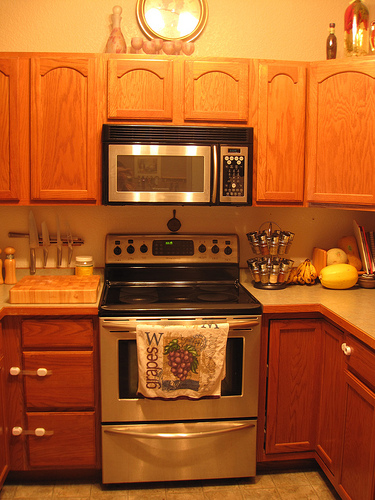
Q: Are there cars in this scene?
A: No, there are no cars.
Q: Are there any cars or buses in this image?
A: No, there are no cars or buses.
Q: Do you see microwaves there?
A: Yes, there is a microwave.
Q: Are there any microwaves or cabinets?
A: Yes, there is a microwave.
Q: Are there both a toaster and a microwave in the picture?
A: No, there is a microwave but no toasters.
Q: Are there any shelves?
A: No, there are no shelves.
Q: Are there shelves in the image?
A: No, there are no shelves.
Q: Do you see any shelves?
A: No, there are no shelves.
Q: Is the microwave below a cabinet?
A: Yes, the microwave is below a cabinet.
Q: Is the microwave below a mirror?
A: No, the microwave is below a cabinet.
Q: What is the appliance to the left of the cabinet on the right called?
A: The appliance is a microwave.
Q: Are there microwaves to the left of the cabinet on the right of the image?
A: Yes, there is a microwave to the left of the cabinet.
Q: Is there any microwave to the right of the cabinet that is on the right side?
A: No, the microwave is to the left of the cabinet.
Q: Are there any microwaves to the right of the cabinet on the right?
A: No, the microwave is to the left of the cabinet.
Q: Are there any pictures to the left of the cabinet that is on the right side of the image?
A: No, there is a microwave to the left of the cabinet.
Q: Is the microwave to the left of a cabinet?
A: Yes, the microwave is to the left of a cabinet.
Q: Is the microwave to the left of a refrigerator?
A: No, the microwave is to the left of a cabinet.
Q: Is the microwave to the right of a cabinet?
A: No, the microwave is to the left of a cabinet.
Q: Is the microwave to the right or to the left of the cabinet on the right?
A: The microwave is to the left of the cabinet.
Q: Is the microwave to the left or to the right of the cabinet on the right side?
A: The microwave is to the left of the cabinet.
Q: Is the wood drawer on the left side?
A: Yes, the drawer is on the left of the image.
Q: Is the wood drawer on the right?
A: No, the drawer is on the left of the image.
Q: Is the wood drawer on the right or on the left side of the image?
A: The drawer is on the left of the image.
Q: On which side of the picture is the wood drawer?
A: The drawer is on the left of the image.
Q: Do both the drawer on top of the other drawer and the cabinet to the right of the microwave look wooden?
A: Yes, both the drawer and the cabinet are wooden.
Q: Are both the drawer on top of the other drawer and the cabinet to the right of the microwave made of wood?
A: Yes, both the drawer and the cabinet are made of wood.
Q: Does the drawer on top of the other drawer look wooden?
A: Yes, the drawer is wooden.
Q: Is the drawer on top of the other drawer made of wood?
A: Yes, the drawer is made of wood.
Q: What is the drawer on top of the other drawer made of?
A: The drawer is made of wood.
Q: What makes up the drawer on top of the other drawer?
A: The drawer is made of wood.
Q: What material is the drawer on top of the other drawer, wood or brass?
A: The drawer is made of wood.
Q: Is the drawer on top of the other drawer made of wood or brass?
A: The drawer is made of wood.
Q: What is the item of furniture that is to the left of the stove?
A: The piece of furniture is a drawer.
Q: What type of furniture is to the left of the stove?
A: The piece of furniture is a drawer.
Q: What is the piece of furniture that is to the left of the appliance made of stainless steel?
A: The piece of furniture is a drawer.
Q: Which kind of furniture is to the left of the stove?
A: The piece of furniture is a drawer.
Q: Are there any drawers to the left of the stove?
A: Yes, there is a drawer to the left of the stove.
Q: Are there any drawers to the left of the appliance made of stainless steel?
A: Yes, there is a drawer to the left of the stove.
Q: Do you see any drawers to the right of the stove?
A: No, the drawer is to the left of the stove.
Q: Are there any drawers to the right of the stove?
A: No, the drawer is to the left of the stove.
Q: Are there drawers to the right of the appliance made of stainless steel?
A: No, the drawer is to the left of the stove.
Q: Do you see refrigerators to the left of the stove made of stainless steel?
A: No, there is a drawer to the left of the stove.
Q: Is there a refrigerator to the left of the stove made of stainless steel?
A: No, there is a drawer to the left of the stove.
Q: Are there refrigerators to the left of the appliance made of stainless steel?
A: No, there is a drawer to the left of the stove.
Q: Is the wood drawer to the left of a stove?
A: Yes, the drawer is to the left of a stove.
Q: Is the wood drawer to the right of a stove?
A: No, the drawer is to the left of a stove.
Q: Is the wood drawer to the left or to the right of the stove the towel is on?
A: The drawer is to the left of the stove.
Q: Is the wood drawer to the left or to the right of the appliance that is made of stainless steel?
A: The drawer is to the left of the stove.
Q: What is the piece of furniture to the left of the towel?
A: The piece of furniture is a drawer.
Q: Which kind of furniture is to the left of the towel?
A: The piece of furniture is a drawer.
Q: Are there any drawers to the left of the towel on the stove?
A: Yes, there is a drawer to the left of the towel.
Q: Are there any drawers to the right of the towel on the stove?
A: No, the drawer is to the left of the towel.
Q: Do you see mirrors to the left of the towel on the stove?
A: No, there is a drawer to the left of the towel.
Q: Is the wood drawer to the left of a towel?
A: Yes, the drawer is to the left of a towel.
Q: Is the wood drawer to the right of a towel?
A: No, the drawer is to the left of a towel.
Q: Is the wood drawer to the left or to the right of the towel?
A: The drawer is to the left of the towel.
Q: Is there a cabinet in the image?
A: Yes, there is a cabinet.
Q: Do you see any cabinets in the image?
A: Yes, there is a cabinet.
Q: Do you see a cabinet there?
A: Yes, there is a cabinet.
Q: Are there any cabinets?
A: Yes, there is a cabinet.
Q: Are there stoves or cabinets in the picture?
A: Yes, there is a cabinet.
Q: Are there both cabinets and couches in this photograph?
A: No, there is a cabinet but no couches.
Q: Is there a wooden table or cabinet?
A: Yes, there is a wood cabinet.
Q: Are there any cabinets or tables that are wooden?
A: Yes, the cabinet is wooden.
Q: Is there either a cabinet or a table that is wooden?
A: Yes, the cabinet is wooden.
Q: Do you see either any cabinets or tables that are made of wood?
A: Yes, the cabinet is made of wood.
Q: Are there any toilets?
A: No, there are no toilets.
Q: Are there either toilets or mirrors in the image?
A: No, there are no toilets or mirrors.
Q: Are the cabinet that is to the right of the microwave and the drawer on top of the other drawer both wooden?
A: Yes, both the cabinet and the drawer are wooden.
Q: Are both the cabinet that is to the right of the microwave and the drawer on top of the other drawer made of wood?
A: Yes, both the cabinet and the drawer are made of wood.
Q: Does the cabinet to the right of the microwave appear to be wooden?
A: Yes, the cabinet is wooden.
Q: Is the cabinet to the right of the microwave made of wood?
A: Yes, the cabinet is made of wood.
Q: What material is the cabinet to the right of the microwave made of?
A: The cabinet is made of wood.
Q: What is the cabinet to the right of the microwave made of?
A: The cabinet is made of wood.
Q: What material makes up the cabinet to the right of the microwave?
A: The cabinet is made of wood.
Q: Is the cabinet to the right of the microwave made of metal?
A: No, the cabinet is made of wood.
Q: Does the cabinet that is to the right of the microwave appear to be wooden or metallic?
A: The cabinet is wooden.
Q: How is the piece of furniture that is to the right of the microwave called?
A: The piece of furniture is a cabinet.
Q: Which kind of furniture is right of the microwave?
A: The piece of furniture is a cabinet.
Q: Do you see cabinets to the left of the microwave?
A: No, the cabinet is to the right of the microwave.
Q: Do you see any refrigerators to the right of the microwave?
A: No, there is a cabinet to the right of the microwave.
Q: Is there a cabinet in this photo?
A: Yes, there is a cabinet.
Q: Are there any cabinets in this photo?
A: Yes, there is a cabinet.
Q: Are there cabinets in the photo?
A: Yes, there is a cabinet.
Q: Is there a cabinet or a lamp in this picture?
A: Yes, there is a cabinet.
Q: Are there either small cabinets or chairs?
A: Yes, there is a small cabinet.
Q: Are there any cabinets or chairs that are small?
A: Yes, the cabinet is small.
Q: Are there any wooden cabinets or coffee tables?
A: Yes, there is a wood cabinet.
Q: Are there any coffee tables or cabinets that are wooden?
A: Yes, the cabinet is wooden.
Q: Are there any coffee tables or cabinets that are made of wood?
A: Yes, the cabinet is made of wood.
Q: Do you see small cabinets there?
A: Yes, there is a small cabinet.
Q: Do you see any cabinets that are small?
A: Yes, there is a small cabinet.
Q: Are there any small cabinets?
A: Yes, there is a small cabinet.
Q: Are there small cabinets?
A: Yes, there is a small cabinet.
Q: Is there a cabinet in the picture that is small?
A: Yes, there is a cabinet that is small.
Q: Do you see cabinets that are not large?
A: Yes, there is a small cabinet.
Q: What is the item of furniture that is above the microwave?
A: The piece of furniture is a cabinet.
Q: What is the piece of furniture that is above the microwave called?
A: The piece of furniture is a cabinet.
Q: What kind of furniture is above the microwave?
A: The piece of furniture is a cabinet.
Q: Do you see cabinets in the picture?
A: Yes, there is a cabinet.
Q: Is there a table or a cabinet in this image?
A: Yes, there is a cabinet.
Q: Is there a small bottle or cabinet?
A: Yes, there is a small cabinet.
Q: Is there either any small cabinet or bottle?
A: Yes, there is a small cabinet.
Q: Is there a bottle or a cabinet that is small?
A: Yes, the cabinet is small.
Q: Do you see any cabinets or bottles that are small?
A: Yes, the cabinet is small.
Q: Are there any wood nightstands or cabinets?
A: Yes, there is a wood cabinet.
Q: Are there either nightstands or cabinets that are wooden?
A: Yes, the cabinet is wooden.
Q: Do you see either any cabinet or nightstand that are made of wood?
A: Yes, the cabinet is made of wood.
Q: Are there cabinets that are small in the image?
A: Yes, there is a small cabinet.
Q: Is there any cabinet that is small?
A: Yes, there is a cabinet that is small.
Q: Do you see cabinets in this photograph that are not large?
A: Yes, there is a small cabinet.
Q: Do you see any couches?
A: No, there are no couches.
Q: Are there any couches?
A: No, there are no couches.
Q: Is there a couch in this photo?
A: No, there are no couches.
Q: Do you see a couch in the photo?
A: No, there are no couches.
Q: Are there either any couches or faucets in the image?
A: No, there are no couches or faucets.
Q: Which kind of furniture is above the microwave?
A: The piece of furniture is a cabinet.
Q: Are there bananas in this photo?
A: Yes, there are bananas.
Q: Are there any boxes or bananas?
A: Yes, there are bananas.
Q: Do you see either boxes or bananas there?
A: Yes, there are bananas.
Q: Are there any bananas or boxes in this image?
A: Yes, there are bananas.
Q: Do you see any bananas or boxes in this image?
A: Yes, there are bananas.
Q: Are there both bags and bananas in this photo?
A: No, there are bananas but no bags.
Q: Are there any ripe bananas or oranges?
A: Yes, there are ripe bananas.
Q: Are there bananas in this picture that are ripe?
A: Yes, there are ripe bananas.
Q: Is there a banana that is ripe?
A: Yes, there are bananas that are ripe.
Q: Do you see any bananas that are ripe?
A: Yes, there are bananas that are ripe.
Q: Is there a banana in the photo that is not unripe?
A: Yes, there are ripe bananas.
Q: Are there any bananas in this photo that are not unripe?
A: Yes, there are ripe bananas.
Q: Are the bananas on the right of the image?
A: Yes, the bananas are on the right of the image.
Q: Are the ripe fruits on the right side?
A: Yes, the bananas are on the right of the image.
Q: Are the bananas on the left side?
A: No, the bananas are on the right of the image.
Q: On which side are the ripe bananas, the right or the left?
A: The bananas are on the right of the image.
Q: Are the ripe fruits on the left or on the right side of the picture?
A: The bananas are on the right of the image.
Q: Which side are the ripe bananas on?
A: The bananas are on the right of the image.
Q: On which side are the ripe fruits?
A: The bananas are on the right of the image.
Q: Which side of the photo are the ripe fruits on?
A: The bananas are on the right of the image.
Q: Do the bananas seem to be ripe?
A: Yes, the bananas are ripe.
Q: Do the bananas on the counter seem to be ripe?
A: Yes, the bananas are ripe.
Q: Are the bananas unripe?
A: No, the bananas are ripe.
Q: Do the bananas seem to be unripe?
A: No, the bananas are ripe.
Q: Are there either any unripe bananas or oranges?
A: No, there are bananas but they are ripe.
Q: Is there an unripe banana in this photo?
A: No, there are bananas but they are ripe.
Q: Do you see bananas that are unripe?
A: No, there are bananas but they are ripe.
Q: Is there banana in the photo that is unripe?
A: No, there are bananas but they are ripe.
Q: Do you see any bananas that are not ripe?
A: No, there are bananas but they are ripe.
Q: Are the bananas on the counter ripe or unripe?
A: The bananas are ripe.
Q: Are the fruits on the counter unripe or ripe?
A: The bananas are ripe.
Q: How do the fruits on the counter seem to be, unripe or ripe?
A: The bananas are ripe.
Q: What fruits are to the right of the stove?
A: The fruits are bananas.